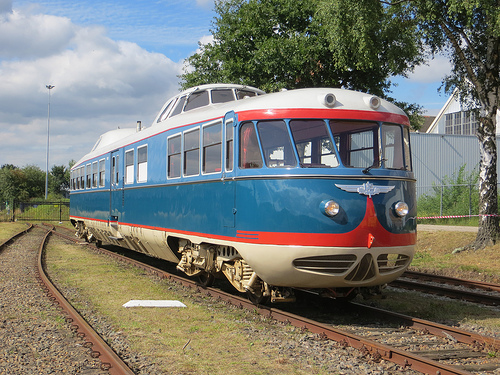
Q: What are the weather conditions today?
A: It is cloudy.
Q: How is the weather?
A: It is cloudy.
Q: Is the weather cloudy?
A: Yes, it is cloudy.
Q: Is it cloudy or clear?
A: It is cloudy.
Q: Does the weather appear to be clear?
A: No, it is cloudy.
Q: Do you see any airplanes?
A: No, there are no airplanes.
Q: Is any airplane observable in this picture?
A: No, there are no airplanes.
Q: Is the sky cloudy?
A: Yes, the sky is cloudy.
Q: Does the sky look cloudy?
A: Yes, the sky is cloudy.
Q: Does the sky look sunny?
A: No, the sky is cloudy.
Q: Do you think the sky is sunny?
A: No, the sky is cloudy.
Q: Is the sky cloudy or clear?
A: The sky is cloudy.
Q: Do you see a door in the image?
A: Yes, there is a door.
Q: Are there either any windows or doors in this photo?
A: Yes, there is a door.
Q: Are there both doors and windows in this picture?
A: Yes, there are both a door and windows.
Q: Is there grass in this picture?
A: Yes, there is grass.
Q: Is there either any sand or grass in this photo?
A: Yes, there is grass.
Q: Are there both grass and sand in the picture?
A: No, there is grass but no sand.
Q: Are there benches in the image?
A: No, there are no benches.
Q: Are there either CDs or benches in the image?
A: No, there are no benches or cds.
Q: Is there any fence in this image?
A: Yes, there is a fence.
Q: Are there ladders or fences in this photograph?
A: Yes, there is a fence.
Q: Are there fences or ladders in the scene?
A: Yes, there is a fence.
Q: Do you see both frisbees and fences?
A: No, there is a fence but no frisbees.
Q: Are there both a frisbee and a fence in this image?
A: No, there is a fence but no frisbees.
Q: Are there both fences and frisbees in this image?
A: No, there is a fence but no frisbees.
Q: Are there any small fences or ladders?
A: Yes, there is a small fence.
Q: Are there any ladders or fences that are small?
A: Yes, the fence is small.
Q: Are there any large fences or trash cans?
A: Yes, there is a large fence.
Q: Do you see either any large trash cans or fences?
A: Yes, there is a large fence.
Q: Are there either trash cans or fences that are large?
A: Yes, the fence is large.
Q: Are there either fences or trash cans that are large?
A: Yes, the fence is large.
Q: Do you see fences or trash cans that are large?
A: Yes, the fence is large.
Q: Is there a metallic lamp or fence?
A: Yes, there is a metal fence.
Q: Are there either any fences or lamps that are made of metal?
A: Yes, the fence is made of metal.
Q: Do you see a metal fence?
A: Yes, there is a metal fence.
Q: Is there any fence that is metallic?
A: Yes, there is a fence that is metallic.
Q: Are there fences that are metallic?
A: Yes, there is a fence that is metallic.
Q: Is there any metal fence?
A: Yes, there is a fence that is made of metal.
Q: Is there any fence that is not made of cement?
A: Yes, there is a fence that is made of metal.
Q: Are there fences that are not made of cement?
A: Yes, there is a fence that is made of metal.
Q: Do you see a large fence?
A: Yes, there is a large fence.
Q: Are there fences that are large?
A: Yes, there is a fence that is large.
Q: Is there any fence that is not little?
A: Yes, there is a large fence.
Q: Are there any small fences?
A: Yes, there is a small fence.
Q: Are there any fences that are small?
A: Yes, there is a fence that is small.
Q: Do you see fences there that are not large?
A: Yes, there is a small fence.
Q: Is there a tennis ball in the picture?
A: No, there are no tennis balls.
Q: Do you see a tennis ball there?
A: No, there are no tennis balls.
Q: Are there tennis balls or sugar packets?
A: No, there are no tennis balls or sugar packets.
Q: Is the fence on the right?
A: Yes, the fence is on the right of the image.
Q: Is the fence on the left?
A: No, the fence is on the right of the image.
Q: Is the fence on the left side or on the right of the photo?
A: The fence is on the right of the image.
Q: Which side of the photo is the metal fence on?
A: The fence is on the right of the image.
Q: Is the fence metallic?
A: Yes, the fence is metallic.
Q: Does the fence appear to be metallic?
A: Yes, the fence is metallic.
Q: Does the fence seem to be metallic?
A: Yes, the fence is metallic.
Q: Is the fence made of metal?
A: Yes, the fence is made of metal.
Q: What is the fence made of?
A: The fence is made of metal.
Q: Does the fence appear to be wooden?
A: No, the fence is metallic.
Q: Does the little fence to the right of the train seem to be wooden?
A: No, the fence is metallic.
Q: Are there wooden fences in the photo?
A: No, there is a fence but it is metallic.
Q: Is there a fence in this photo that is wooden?
A: No, there is a fence but it is metallic.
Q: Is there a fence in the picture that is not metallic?
A: No, there is a fence but it is metallic.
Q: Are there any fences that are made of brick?
A: No, there is a fence but it is made of metal.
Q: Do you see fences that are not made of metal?
A: No, there is a fence but it is made of metal.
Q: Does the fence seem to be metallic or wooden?
A: The fence is metallic.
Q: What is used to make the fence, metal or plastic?
A: The fence is made of metal.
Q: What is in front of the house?
A: The fence is in front of the house.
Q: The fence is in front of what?
A: The fence is in front of the house.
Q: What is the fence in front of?
A: The fence is in front of the house.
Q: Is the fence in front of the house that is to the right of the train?
A: Yes, the fence is in front of the house.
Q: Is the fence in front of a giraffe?
A: No, the fence is in front of the house.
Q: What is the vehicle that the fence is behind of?
A: The vehicle is a train.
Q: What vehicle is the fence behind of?
A: The fence is behind the train.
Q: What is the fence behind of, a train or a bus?
A: The fence is behind a train.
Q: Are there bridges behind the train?
A: No, there is a fence behind the train.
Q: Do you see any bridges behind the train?
A: No, there is a fence behind the train.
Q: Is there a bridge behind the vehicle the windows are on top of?
A: No, there is a fence behind the train.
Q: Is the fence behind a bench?
A: No, the fence is behind a train.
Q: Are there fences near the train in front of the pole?
A: Yes, there is a fence near the train.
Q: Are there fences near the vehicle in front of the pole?
A: Yes, there is a fence near the train.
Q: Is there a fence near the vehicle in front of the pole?
A: Yes, there is a fence near the train.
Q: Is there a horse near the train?
A: No, there is a fence near the train.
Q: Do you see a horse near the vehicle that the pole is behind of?
A: No, there is a fence near the train.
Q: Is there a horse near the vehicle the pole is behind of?
A: No, there is a fence near the train.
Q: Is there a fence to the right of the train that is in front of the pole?
A: Yes, there is a fence to the right of the train.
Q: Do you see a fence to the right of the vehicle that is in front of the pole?
A: Yes, there is a fence to the right of the train.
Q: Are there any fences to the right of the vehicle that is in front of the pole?
A: Yes, there is a fence to the right of the train.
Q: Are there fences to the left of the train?
A: No, the fence is to the right of the train.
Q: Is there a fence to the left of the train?
A: No, the fence is to the right of the train.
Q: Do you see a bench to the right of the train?
A: No, there is a fence to the right of the train.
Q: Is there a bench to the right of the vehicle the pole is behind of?
A: No, there is a fence to the right of the train.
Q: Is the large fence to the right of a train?
A: Yes, the fence is to the right of a train.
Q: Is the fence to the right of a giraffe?
A: No, the fence is to the right of a train.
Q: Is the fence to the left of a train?
A: No, the fence is to the right of a train.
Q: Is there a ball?
A: No, there are no balls.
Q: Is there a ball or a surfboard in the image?
A: No, there are no balls or surfboards.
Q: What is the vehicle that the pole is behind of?
A: The vehicle is a train.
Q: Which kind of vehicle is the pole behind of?
A: The pole is behind the train.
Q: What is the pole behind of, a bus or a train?
A: The pole is behind a train.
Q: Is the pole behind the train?
A: Yes, the pole is behind the train.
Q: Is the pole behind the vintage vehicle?
A: Yes, the pole is behind the train.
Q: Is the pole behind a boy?
A: No, the pole is behind the train.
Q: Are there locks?
A: No, there are no locks.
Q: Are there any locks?
A: No, there are no locks.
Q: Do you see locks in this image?
A: No, there are no locks.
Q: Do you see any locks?
A: No, there are no locks.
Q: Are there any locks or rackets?
A: No, there are no locks or rackets.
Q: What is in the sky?
A: The clouds are in the sky.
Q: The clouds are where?
A: The clouds are in the sky.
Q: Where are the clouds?
A: The clouds are in the sky.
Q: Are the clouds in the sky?
A: Yes, the clouds are in the sky.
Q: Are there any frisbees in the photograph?
A: No, there are no frisbees.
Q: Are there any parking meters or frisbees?
A: No, there are no frisbees or parking meters.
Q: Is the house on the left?
A: No, the house is on the right of the image.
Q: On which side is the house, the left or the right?
A: The house is on the right of the image.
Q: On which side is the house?
A: The house is on the right of the image.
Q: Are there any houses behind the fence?
A: Yes, there is a house behind the fence.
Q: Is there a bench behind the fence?
A: No, there is a house behind the fence.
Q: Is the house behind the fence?
A: Yes, the house is behind the fence.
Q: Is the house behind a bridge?
A: No, the house is behind the fence.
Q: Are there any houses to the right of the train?
A: Yes, there is a house to the right of the train.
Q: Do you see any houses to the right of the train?
A: Yes, there is a house to the right of the train.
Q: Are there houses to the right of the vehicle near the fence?
A: Yes, there is a house to the right of the train.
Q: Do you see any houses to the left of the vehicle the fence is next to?
A: No, the house is to the right of the train.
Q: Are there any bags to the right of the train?
A: No, there is a house to the right of the train.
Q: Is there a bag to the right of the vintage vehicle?
A: No, there is a house to the right of the train.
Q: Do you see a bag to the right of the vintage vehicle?
A: No, there is a house to the right of the train.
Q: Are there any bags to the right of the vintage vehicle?
A: No, there is a house to the right of the train.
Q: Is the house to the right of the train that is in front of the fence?
A: Yes, the house is to the right of the train.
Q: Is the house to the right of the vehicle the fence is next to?
A: Yes, the house is to the right of the train.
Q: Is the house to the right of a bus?
A: No, the house is to the right of the train.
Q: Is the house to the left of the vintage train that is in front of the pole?
A: No, the house is to the right of the train.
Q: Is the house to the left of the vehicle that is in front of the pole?
A: No, the house is to the right of the train.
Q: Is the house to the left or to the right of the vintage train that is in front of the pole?
A: The house is to the right of the train.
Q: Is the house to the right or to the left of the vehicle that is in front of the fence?
A: The house is to the right of the train.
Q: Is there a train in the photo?
A: Yes, there is a train.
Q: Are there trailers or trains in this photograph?
A: Yes, there is a train.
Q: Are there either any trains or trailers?
A: Yes, there is a train.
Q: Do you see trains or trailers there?
A: Yes, there is a train.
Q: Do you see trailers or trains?
A: Yes, there is a train.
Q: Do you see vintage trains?
A: Yes, there is a vintage train.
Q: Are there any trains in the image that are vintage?
A: Yes, there is a train that is vintage.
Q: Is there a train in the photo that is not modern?
A: Yes, there is a vintage train.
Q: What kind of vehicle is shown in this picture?
A: The vehicle is a train.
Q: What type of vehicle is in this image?
A: The vehicle is a train.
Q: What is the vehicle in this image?
A: The vehicle is a train.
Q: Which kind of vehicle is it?
A: The vehicle is a train.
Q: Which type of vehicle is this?
A: This is a train.